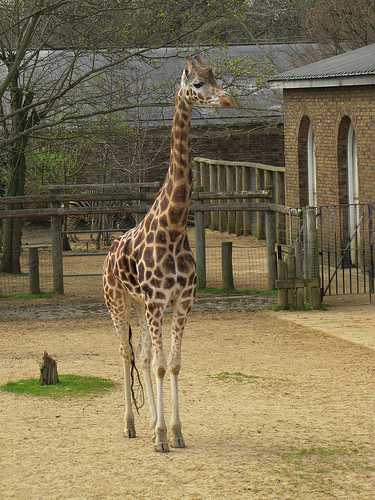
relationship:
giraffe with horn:
[102, 58, 237, 454] [184, 53, 194, 69]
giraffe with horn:
[102, 58, 237, 454] [191, 54, 205, 68]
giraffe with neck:
[102, 58, 237, 454] [143, 78, 194, 234]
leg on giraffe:
[166, 263, 200, 452] [102, 58, 237, 454]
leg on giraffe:
[137, 257, 172, 454] [102, 58, 237, 454]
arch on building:
[334, 109, 362, 272] [263, 46, 363, 273]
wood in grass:
[37, 349, 61, 385] [0, 372, 122, 404]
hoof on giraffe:
[168, 431, 189, 449] [102, 58, 237, 454]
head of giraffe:
[174, 53, 238, 113] [102, 58, 237, 454]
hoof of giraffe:
[150, 436, 171, 453] [102, 58, 237, 454]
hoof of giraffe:
[168, 434, 190, 451] [102, 58, 237, 454]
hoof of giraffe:
[120, 423, 139, 441] [102, 58, 237, 454]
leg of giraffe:
[143, 301, 169, 442] [102, 58, 237, 454]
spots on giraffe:
[133, 242, 173, 290] [102, 58, 237, 454]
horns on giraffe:
[183, 52, 204, 71] [102, 58, 237, 454]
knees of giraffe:
[152, 357, 185, 378] [102, 58, 237, 454]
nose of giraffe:
[219, 94, 233, 104] [102, 58, 237, 454]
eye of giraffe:
[188, 79, 207, 92] [102, 58, 237, 454]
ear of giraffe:
[178, 65, 191, 84] [102, 58, 237, 454]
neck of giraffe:
[144, 78, 198, 232] [102, 58, 237, 454]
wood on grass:
[33, 349, 64, 385] [0, 371, 123, 401]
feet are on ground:
[123, 411, 191, 452] [220, 385, 312, 451]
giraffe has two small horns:
[102, 58, 237, 454] [183, 55, 206, 69]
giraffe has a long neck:
[103, 58, 215, 448] [167, 100, 194, 192]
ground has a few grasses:
[238, 412, 350, 479] [15, 383, 99, 396]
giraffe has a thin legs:
[102, 58, 237, 454] [113, 310, 190, 449]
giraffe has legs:
[103, 58, 215, 448] [113, 310, 190, 449]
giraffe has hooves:
[102, 58, 237, 454] [148, 419, 188, 451]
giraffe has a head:
[103, 58, 215, 448] [169, 51, 231, 111]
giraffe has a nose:
[103, 58, 215, 448] [216, 90, 231, 97]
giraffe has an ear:
[103, 58, 215, 448] [179, 68, 191, 83]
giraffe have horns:
[103, 58, 215, 448] [187, 51, 204, 70]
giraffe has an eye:
[103, 58, 215, 448] [191, 76, 205, 90]